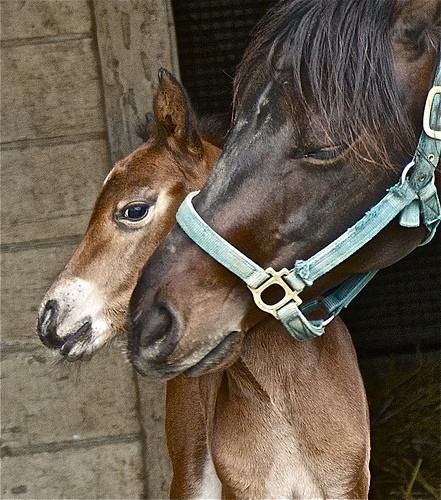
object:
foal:
[33, 66, 372, 498]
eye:
[113, 199, 153, 226]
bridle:
[173, 57, 440, 343]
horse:
[126, 3, 437, 383]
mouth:
[34, 312, 95, 366]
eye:
[289, 133, 362, 172]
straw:
[372, 351, 441, 499]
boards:
[0, 1, 179, 499]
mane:
[230, 0, 431, 174]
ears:
[150, 68, 204, 161]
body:
[163, 299, 371, 498]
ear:
[148, 64, 205, 163]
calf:
[36, 68, 373, 499]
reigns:
[122, 59, 440, 386]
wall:
[1, 1, 181, 500]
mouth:
[132, 329, 243, 382]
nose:
[30, 297, 61, 342]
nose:
[124, 289, 186, 372]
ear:
[392, 0, 440, 51]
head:
[125, 1, 438, 382]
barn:
[4, 0, 438, 500]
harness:
[245, 264, 303, 321]